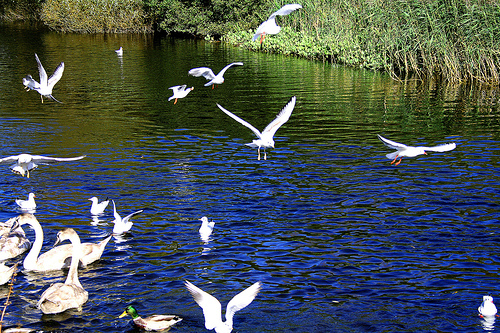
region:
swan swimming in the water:
[16, 209, 110, 309]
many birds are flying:
[146, 57, 434, 202]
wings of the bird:
[215, 90, 312, 132]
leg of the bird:
[253, 150, 273, 162]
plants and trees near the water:
[326, 15, 488, 80]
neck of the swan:
[30, 220, 42, 260]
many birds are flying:
[20, 40, 337, 185]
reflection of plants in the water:
[280, 52, 357, 90]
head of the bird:
[118, 298, 138, 320]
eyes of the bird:
[56, 230, 63, 243]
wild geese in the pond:
[38, 227, 89, 316]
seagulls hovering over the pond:
[214, 96, 296, 163]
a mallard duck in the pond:
[117, 304, 183, 331]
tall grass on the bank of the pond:
[312, 0, 494, 80]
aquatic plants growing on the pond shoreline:
[1, 0, 498, 75]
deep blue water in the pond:
[262, 180, 479, 331]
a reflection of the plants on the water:
[319, 82, 498, 133]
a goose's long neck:
[10, 212, 45, 269]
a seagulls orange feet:
[391, 150, 403, 167]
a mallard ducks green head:
[116, 304, 139, 319]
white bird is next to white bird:
[21, 50, 67, 108]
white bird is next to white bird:
[169, 80, 196, 104]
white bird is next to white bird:
[190, 61, 245, 89]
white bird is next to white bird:
[373, 131, 458, 171]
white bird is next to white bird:
[248, 1, 305, 49]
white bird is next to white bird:
[195, 212, 219, 244]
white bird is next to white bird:
[184, 282, 256, 331]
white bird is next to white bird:
[108, 206, 146, 242]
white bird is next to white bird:
[0, 153, 89, 178]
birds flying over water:
[0, 10, 451, 279]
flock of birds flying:
[93, 15, 455, 221]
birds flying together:
[0, 10, 361, 214]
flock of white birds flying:
[1, 9, 334, 216]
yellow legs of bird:
[248, 148, 269, 163]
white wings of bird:
[213, 90, 309, 142]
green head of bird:
[125, 299, 137, 319]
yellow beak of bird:
[115, 310, 130, 322]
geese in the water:
[0, 200, 124, 325]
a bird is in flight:
[215, 93, 295, 161]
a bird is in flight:
[375, 131, 457, 168]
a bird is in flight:
[191, 62, 242, 91]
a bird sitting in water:
[474, 292, 496, 322]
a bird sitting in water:
[193, 213, 218, 239]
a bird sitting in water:
[86, 196, 111, 220]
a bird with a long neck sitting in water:
[40, 225, 89, 318]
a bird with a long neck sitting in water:
[10, 211, 109, 272]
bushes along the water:
[38, 4, 498, 86]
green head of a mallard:
[117, 306, 137, 319]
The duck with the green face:
[117, 302, 182, 330]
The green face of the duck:
[124, 302, 139, 322]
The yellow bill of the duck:
[118, 309, 128, 319]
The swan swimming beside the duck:
[34, 223, 91, 318]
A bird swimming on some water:
[119, 304, 181, 331]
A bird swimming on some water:
[195, 215, 216, 238]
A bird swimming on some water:
[478, 294, 499, 316]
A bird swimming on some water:
[88, 195, 111, 215]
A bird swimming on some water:
[38, 227, 87, 314]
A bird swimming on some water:
[11, 212, 113, 273]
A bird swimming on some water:
[0, 215, 32, 260]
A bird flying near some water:
[216, 94, 296, 159]